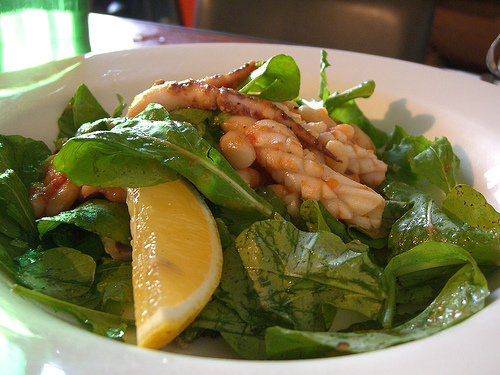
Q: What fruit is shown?
A: A lemon.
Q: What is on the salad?
A: Meat.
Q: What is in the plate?
A: Salad.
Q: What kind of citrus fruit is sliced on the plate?
A: Lemon.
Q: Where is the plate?
A: On a table.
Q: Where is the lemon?
A: In the salad.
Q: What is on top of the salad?
A: Meat.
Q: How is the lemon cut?
A: Sliced.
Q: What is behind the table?
A: A chair.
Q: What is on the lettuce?
A: Dressing.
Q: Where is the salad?
A: On the table.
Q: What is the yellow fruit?
A: Lemon.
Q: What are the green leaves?
A: Spinach.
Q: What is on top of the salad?
A: Chicken.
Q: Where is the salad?
A: In the bowl.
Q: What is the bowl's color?
A: White.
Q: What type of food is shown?
A: Salad.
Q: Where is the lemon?
A: In the salad.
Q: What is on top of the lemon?
A: Spinach leaf.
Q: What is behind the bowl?
A: Chair.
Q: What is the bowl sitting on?
A: Table.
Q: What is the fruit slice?
A: Lemon.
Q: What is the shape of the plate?
A: Round.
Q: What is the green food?
A: Spinach and other greens.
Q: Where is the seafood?
A: On top of greens.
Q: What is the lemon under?
A: Spinach.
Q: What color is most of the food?
A: Green.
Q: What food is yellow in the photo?
A: A lemon.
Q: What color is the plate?
A: White.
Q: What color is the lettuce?
A: Green.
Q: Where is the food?
A: In a plate.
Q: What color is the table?
A: Brown.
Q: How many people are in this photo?
A: None.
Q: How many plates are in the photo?
A: One.